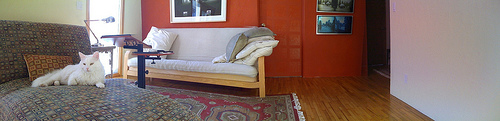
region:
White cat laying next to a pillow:
[30, 52, 110, 89]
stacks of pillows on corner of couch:
[221, 23, 273, 69]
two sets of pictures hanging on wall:
[312, 2, 356, 35]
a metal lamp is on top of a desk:
[83, 17, 115, 49]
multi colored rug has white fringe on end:
[203, 88, 303, 119]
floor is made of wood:
[309, 81, 391, 118]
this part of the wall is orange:
[299, 37, 364, 76]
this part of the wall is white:
[402, 13, 483, 100]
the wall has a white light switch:
[387, 1, 400, 16]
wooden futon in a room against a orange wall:
[126, 24, 278, 96]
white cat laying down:
[29, 50, 104, 86]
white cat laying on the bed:
[26, 45, 106, 87]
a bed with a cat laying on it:
[0, 20, 204, 119]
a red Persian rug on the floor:
[135, 83, 307, 120]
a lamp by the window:
[80, 15, 112, 45]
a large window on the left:
[87, 0, 124, 77]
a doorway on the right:
[365, 0, 390, 87]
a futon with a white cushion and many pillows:
[126, 28, 265, 96]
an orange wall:
[141, 1, 365, 78]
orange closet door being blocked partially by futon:
[260, 0, 301, 79]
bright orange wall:
[247, 0, 374, 79]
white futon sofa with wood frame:
[129, 21, 281, 88]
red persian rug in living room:
[205, 84, 315, 118]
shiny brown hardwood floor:
[303, 84, 365, 117]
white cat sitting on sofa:
[27, 38, 125, 88]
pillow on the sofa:
[18, 39, 80, 87]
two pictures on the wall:
[311, 0, 358, 51]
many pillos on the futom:
[143, 24, 285, 73]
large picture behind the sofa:
[157, 0, 269, 36]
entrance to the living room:
[358, 2, 405, 107]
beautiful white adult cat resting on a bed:
[30, 51, 107, 89]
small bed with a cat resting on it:
[1, 18, 197, 119]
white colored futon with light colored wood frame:
[121, 23, 278, 98]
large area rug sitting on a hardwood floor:
[106, 73, 303, 120]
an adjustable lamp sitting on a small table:
[84, 15, 115, 48]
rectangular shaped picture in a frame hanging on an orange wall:
[314, 12, 354, 35]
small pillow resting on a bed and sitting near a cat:
[23, 51, 74, 83]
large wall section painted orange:
[139, 0, 372, 80]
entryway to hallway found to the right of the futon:
[363, 1, 391, 95]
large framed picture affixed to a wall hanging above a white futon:
[168, 0, 228, 24]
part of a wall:
[471, 29, 496, 34]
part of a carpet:
[282, 99, 291, 116]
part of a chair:
[246, 46, 255, 61]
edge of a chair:
[213, 33, 220, 47]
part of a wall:
[432, 45, 448, 70]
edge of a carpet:
[287, 84, 288, 106]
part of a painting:
[216, 3, 235, 20]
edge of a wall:
[405, 25, 432, 76]